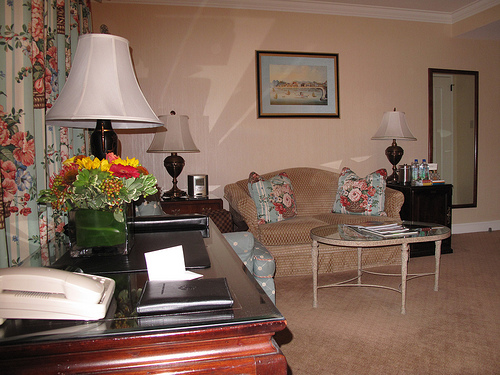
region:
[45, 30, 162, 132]
white lampshade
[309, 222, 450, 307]
glass top coffee table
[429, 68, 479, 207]
mirror on the wall with a dark colored border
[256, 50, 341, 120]
painting hanging on the wall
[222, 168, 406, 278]
tan couch behind the coffee table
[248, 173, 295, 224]
blue pillow on the left side of the couch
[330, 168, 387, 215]
blue pillow on the right side of the couch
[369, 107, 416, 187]
lamp with white lamp shade next to the couch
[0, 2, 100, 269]
curtains with a floral pattern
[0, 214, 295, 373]
wooden table with flowers, a lamp, and a telephone on it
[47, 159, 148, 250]
flowers in the vase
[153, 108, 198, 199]
lamp on the table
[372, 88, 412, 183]
lamp on the table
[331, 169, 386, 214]
pillow on the couch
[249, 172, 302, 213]
pillow on the couch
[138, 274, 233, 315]
notepad on the table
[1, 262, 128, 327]
phone on the table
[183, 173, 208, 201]
clock on the table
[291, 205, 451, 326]
coffee table on the floor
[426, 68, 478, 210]
a mirror with a brown wooden frame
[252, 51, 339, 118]
a picture of the wall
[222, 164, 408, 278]
a small tan love seat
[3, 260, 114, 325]
a white corded phone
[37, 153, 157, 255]
a green vase of flowers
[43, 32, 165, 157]
a brown lamp with a white shade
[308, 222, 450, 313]
an oval glass top table with magazines on top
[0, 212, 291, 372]
a brown wooden table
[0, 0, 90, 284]
white curtains with a floral pattern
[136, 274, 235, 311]
a black book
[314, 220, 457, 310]
TABLE IN THE MIDDLE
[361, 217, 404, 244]
PAPER ON THE TABLE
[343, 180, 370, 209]
FLOWERS ON THE PILLOW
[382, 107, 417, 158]
LAMP ON THE TABLE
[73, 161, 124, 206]
FLOWERS IN A VASE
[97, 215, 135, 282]
VASE ON THE TABLE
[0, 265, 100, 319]
PHONE ON THE TOP GLASS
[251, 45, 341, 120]
a large picture frame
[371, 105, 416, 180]
a tall table lamp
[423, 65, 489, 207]
a long wall mirror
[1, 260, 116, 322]
part of a white phone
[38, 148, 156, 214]
colorful flowers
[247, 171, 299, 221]
a colorful pillow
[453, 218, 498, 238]
part of a white floor trim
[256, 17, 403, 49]
part of a painted wall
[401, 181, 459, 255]
a living room side table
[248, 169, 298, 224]
blue throw pillow with flowers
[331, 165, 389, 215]
blue throw pillow with flowers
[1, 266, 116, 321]
white corded land line telephone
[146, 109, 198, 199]
table lamp with a light colored shade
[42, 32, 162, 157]
table lamp with a light colored shade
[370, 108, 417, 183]
table lamp with a light colored shade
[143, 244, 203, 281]
white note card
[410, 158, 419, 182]
bottle of water on a side table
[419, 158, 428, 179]
bottle of water on a side table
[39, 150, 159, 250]
flowers inside of green vase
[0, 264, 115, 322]
white telephone receiver and base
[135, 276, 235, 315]
shiny black leather paper book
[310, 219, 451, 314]
oval shaped beige and glass coffee table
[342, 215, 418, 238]
magazines laid out on coffee table